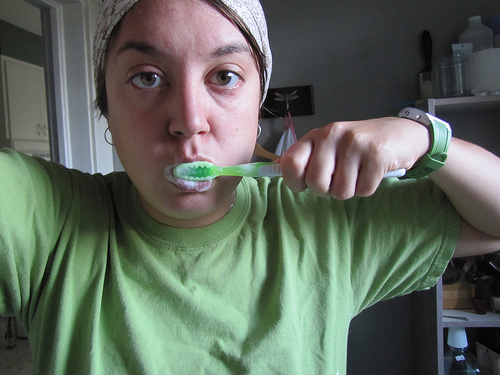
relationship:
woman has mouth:
[1, 0, 498, 372] [165, 156, 217, 192]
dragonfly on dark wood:
[272, 86, 301, 108] [292, 101, 318, 116]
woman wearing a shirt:
[1, 0, 498, 372] [39, 164, 389, 352]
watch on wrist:
[381, 103, 455, 204] [397, 108, 455, 181]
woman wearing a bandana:
[1, 0, 498, 372] [205, 6, 277, 48]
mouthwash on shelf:
[444, 329, 482, 371] [441, 307, 484, 370]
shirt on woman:
[2, 153, 449, 371] [1, 0, 498, 372]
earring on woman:
[103, 126, 116, 146] [1, 0, 498, 372]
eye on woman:
[123, 62, 168, 89] [1, 0, 498, 372]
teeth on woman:
[174, 160, 283, 179] [1, 0, 498, 372]